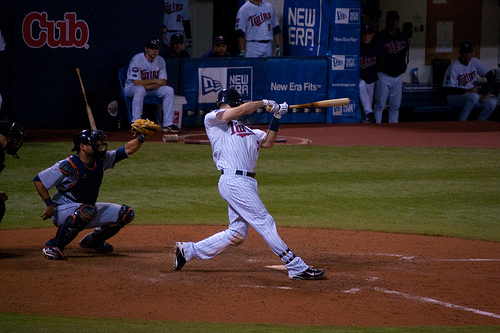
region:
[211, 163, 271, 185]
black belt looped in belt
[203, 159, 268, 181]
white loop in white pants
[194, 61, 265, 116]
blue and white symbol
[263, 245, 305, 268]
double black bands around player's leg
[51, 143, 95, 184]
blue and red protection vest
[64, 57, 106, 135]
brown bat leaning against wall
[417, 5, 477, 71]
large brown board in dugout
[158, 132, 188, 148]
white can on ground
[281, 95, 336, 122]
red portion of brown bat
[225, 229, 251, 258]
dirt on pants knee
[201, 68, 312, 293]
baseball player swinging a bat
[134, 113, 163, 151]
catcher's mitt in left hand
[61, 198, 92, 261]
shin guards on right leg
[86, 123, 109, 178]
catcher has face mask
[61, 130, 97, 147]
hat is on backwards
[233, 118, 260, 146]
name of team on front shirt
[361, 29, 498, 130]
players watching batter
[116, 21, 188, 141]
boy sitting on a chair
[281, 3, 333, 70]
logo on the banner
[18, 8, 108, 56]
red letters on the board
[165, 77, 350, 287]
man wearing a helmet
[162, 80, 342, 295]
man wearing stripe shirt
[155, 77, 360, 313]
man wearing stripe pants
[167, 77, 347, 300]
man holding a bat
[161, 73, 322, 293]
man wearing black shoes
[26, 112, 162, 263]
man wearing mask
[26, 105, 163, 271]
man holding a glove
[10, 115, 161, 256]
man wearing blue shirt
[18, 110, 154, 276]
man wearing blue pants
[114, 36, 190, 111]
man wearing a cap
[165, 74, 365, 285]
batter swinging the bat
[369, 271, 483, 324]
white chalk line down the base line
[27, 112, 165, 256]
catcher with his mitt extended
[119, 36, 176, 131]
player sitting in a blue chair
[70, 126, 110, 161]
catcher wearing a helmet and mask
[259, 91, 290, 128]
batter using batting gloves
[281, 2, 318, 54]
advertisement on the blue tarp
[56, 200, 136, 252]
catcher wearing knee and shin guards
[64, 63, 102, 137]
bat leaning up against the wall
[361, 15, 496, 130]
players in the dug out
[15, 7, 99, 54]
bold red text print on a wall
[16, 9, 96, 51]
bold red print on a wall reading Cub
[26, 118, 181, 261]
baseball catcher with his gloved hand up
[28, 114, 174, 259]
baseball player preparing to catch a ball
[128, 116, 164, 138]
brown mitt on a catcher's hand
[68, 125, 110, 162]
protective gear covering a catcher's face and head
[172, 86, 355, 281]
baseball player swinging his bat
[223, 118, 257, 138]
red print on a baseball jersey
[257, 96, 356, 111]
bat in a baseball player's hand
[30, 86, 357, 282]
two baseball player's on a field